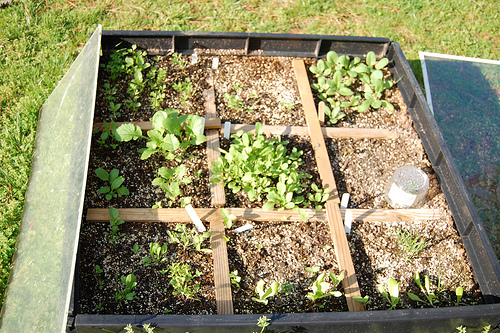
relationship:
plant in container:
[113, 108, 209, 159] [89, 33, 493, 332]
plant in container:
[252, 272, 296, 317] [89, 33, 493, 332]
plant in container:
[309, 276, 340, 296] [89, 33, 493, 332]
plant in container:
[376, 276, 402, 303] [89, 33, 493, 332]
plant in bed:
[210, 122, 330, 222] [0, 23, 500, 333]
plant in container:
[101, 45, 213, 132] [89, 33, 493, 332]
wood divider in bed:
[292, 54, 364, 308] [0, 23, 500, 333]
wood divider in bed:
[195, 51, 237, 314] [0, 23, 500, 333]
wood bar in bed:
[94, 122, 397, 139] [0, 23, 500, 333]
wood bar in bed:
[90, 208, 439, 219] [0, 23, 500, 333]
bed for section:
[0, 23, 500, 333] [74, 217, 214, 313]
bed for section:
[0, 23, 500, 333] [225, 217, 346, 317]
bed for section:
[0, 23, 500, 333] [343, 215, 483, 305]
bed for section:
[0, 23, 500, 333] [88, 125, 210, 208]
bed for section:
[0, 23, 500, 333] [221, 130, 328, 208]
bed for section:
[0, 23, 500, 333] [325, 134, 451, 211]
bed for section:
[0, 23, 500, 333] [93, 47, 207, 117]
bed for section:
[0, 23, 500, 333] [212, 57, 305, 126]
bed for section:
[0, 23, 500, 333] [306, 57, 414, 132]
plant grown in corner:
[311, 49, 402, 125] [305, 37, 415, 133]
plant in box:
[101, 45, 194, 122] [77, 26, 499, 332]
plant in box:
[217, 130, 324, 198] [77, 26, 499, 332]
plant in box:
[100, 110, 205, 204] [77, 26, 499, 332]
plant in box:
[307, 49, 409, 122] [77, 26, 499, 332]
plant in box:
[364, 225, 474, 302] [77, 26, 499, 332]